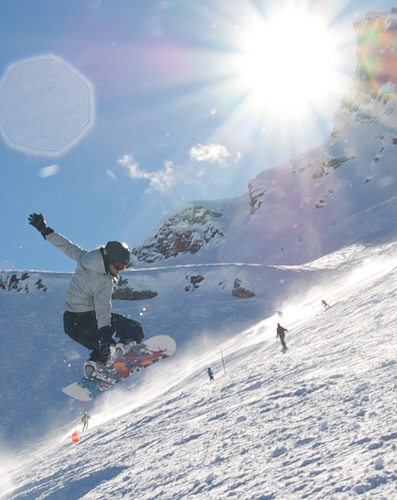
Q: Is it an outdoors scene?
A: Yes, it is outdoors.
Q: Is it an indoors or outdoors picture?
A: It is outdoors.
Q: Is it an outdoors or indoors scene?
A: It is outdoors.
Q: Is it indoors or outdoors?
A: It is outdoors.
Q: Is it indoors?
A: No, it is outdoors.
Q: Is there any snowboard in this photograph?
A: Yes, there is a snowboard.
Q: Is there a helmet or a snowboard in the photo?
A: Yes, there is a snowboard.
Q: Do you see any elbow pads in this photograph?
A: No, there are no elbow pads.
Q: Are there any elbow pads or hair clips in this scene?
A: No, there are no elbow pads or hair clips.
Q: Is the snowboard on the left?
A: Yes, the snowboard is on the left of the image.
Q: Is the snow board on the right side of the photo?
A: No, the snow board is on the left of the image.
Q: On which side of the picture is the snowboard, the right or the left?
A: The snowboard is on the left of the image.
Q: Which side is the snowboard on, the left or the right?
A: The snowboard is on the left of the image.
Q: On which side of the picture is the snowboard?
A: The snowboard is on the left of the image.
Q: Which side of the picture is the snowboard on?
A: The snowboard is on the left of the image.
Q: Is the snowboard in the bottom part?
A: Yes, the snowboard is in the bottom of the image.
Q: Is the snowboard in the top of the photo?
A: No, the snowboard is in the bottom of the image.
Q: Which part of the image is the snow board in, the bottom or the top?
A: The snow board is in the bottom of the image.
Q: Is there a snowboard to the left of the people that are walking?
A: Yes, there is a snowboard to the left of the people.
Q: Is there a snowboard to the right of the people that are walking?
A: No, the snowboard is to the left of the people.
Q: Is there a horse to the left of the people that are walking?
A: No, there is a snowboard to the left of the people.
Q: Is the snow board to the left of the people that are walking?
A: Yes, the snow board is to the left of the people.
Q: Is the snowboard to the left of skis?
A: No, the snowboard is to the left of the people.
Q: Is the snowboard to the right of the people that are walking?
A: No, the snowboard is to the left of the people.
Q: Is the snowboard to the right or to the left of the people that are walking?
A: The snowboard is to the left of the people.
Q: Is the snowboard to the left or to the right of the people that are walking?
A: The snowboard is to the left of the people.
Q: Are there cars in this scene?
A: No, there are no cars.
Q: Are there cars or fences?
A: No, there are no cars or fences.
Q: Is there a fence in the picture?
A: No, there are no fences.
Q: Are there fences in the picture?
A: No, there are no fences.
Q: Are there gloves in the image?
A: Yes, there are gloves.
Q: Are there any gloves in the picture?
A: Yes, there are gloves.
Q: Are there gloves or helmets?
A: Yes, there are gloves.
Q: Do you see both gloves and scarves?
A: No, there are gloves but no scarves.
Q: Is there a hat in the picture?
A: No, there are no hats.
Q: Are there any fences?
A: No, there are no fences.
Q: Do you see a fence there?
A: No, there are no fences.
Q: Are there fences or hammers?
A: No, there are no fences or hammers.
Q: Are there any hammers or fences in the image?
A: No, there are no fences or hammers.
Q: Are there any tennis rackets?
A: No, there are no tennis rackets.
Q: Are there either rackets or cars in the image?
A: No, there are no rackets or cars.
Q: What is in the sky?
A: The clouds are in the sky.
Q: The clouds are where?
A: The clouds are in the sky.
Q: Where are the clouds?
A: The clouds are in the sky.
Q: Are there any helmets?
A: Yes, there is a helmet.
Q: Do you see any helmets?
A: Yes, there is a helmet.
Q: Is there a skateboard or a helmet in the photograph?
A: Yes, there is a helmet.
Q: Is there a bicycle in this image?
A: No, there are no bicycles.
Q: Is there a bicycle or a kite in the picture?
A: No, there are no bicycles or kites.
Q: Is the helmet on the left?
A: Yes, the helmet is on the left of the image.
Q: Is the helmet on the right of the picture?
A: No, the helmet is on the left of the image.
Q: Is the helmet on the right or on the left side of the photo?
A: The helmet is on the left of the image.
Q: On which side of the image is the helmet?
A: The helmet is on the left of the image.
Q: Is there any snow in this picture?
A: Yes, there is snow.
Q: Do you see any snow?
A: Yes, there is snow.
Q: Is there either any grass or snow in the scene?
A: Yes, there is snow.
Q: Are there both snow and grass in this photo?
A: No, there is snow but no grass.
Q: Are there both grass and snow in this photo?
A: No, there is snow but no grass.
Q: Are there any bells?
A: No, there are no bells.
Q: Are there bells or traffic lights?
A: No, there are no bells or traffic lights.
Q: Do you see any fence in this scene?
A: No, there are no fences.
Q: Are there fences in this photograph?
A: No, there are no fences.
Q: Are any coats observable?
A: Yes, there is a coat.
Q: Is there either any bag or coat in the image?
A: Yes, there is a coat.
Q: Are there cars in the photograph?
A: No, there are no cars.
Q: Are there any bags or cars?
A: No, there are no cars or bags.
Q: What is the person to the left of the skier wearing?
A: The person is wearing a coat.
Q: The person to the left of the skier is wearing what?
A: The person is wearing a coat.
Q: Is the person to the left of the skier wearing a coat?
A: Yes, the person is wearing a coat.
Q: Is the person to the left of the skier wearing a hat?
A: No, the person is wearing a coat.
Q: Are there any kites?
A: No, there are no kites.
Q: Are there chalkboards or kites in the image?
A: No, there are no kites or chalkboards.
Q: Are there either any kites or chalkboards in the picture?
A: No, there are no kites or chalkboards.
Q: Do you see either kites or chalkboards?
A: No, there are no kites or chalkboards.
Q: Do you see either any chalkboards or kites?
A: No, there are no kites or chalkboards.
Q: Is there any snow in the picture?
A: Yes, there is snow.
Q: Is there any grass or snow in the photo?
A: Yes, there is snow.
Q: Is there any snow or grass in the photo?
A: Yes, there is snow.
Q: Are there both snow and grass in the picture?
A: No, there is snow but no grass.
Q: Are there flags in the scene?
A: No, there are no flags.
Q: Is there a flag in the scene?
A: No, there are no flags.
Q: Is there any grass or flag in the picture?
A: No, there are no flags or grass.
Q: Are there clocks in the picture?
A: No, there are no clocks.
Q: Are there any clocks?
A: No, there are no clocks.